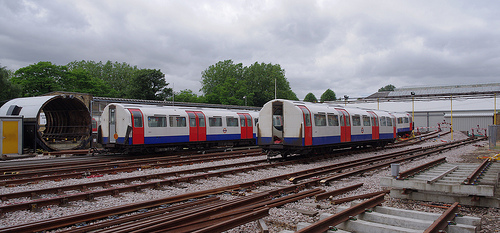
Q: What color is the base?
A: Blue.